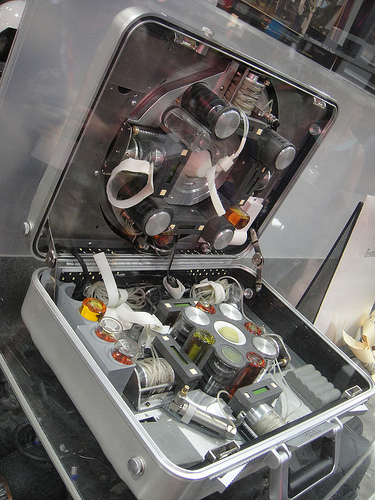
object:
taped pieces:
[106, 157, 154, 208]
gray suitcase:
[19, 4, 373, 498]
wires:
[13, 419, 66, 461]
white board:
[313, 192, 374, 346]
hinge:
[46, 247, 59, 270]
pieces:
[193, 328, 216, 344]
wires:
[150, 344, 156, 386]